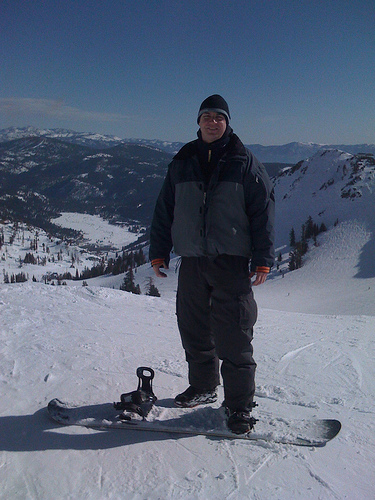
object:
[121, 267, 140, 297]
green tree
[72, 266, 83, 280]
green tree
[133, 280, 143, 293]
green tree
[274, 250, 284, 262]
green tree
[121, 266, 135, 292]
green tree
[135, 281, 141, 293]
green tree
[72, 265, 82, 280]
green tree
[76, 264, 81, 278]
green tree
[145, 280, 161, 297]
green tree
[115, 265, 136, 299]
green tree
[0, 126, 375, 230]
mountains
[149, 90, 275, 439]
guy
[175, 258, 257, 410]
jacket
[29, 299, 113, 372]
snow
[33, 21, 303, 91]
blue sky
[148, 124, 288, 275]
coat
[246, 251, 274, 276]
cuff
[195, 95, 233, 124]
cap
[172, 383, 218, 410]
boots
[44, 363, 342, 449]
ski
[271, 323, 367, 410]
snow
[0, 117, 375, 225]
hill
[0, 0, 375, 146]
sky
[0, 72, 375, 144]
clouds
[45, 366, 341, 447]
snowboard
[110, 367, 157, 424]
foot brace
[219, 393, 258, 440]
boots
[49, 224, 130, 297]
trees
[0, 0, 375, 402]
background